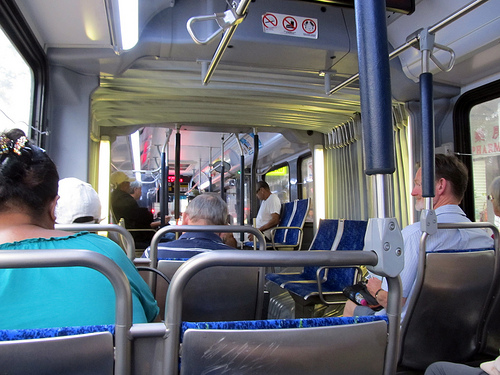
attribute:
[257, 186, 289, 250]
shirt — white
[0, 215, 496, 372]
seats — metal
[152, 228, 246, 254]
shirt — blue, white, striped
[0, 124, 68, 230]
hair — brown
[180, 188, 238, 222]
hair — gray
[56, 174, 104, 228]
hat — white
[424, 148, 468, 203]
hair — brown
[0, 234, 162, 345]
shirt — teal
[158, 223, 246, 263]
shirt — blue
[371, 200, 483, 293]
shirt — light colored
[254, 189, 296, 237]
shirt — white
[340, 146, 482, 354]
man — old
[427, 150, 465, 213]
hair — black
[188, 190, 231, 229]
hair — light gray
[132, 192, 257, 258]
man — old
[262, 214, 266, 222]
shirt — white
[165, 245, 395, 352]
bench — blue and grey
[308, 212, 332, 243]
bench — blue and grey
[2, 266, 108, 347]
shirt — blue 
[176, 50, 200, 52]
safety handle — white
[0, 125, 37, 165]
hair — brown and tied with butterfly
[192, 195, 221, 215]
hair — grey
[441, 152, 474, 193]
hair — brown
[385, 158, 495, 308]
person — sitting down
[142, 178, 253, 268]
person — sitting down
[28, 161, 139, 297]
person — sitting down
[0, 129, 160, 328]
person — sitting down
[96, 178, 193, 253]
person — sitting down